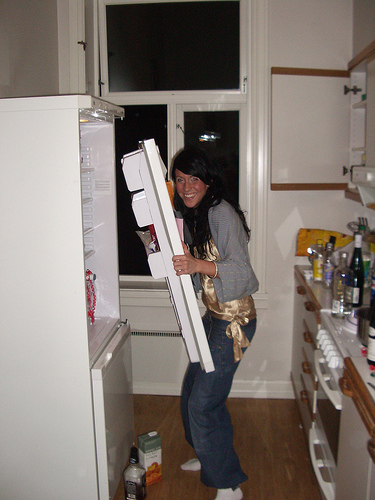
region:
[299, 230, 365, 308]
several bottles on a counter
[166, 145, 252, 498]
woman with dark hair laughing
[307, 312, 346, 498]
an oven door that is white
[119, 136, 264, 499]
woman holding refrigerator door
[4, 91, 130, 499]
refrigerator without a door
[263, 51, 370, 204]
cabinet door that is open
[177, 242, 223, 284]
bracelet on a wrist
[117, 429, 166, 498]
containers on a floor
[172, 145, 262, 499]
woman in white socks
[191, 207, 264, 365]
gold shirt with a bow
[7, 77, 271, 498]
woman in front a refrigerator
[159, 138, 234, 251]
happy woman is smiling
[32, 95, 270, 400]
woman holds a door of refrigerator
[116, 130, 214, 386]
a white door of refrigerator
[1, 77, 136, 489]
the refrigerator is color white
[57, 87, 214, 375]
door of freezer of refrigerator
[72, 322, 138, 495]
door of lower part of refrigerator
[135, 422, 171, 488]
a box of juice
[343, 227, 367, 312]
a bottle of wine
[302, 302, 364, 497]
a stove with white handles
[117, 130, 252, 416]
a woman holding a refrigerator door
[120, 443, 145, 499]
a bottle of alcohol on the floor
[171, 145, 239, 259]
a woman with black hair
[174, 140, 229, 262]
a woman with long hair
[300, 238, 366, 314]
several bottles of on a counter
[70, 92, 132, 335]
a refrigerator with the door off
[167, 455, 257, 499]
a woman wearing white socks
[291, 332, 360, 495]
a white stove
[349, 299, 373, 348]
a silver pot on a stove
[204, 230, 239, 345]
a woman wearing a gold shirt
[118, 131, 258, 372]
Broken refrigerator door held away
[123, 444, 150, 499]
Colorless bottle with a black top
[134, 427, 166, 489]
Box sachet with multiple colors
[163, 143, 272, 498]
Smiling long haired woman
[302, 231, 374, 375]
Bottles arranged on top of a cabinet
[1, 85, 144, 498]
Large refrigerator without an upper door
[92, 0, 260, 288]
Glass window with white panels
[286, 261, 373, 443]
Large cabinet with brown drawer handles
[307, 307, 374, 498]
Cooker unit with white knob controls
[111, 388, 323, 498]
Smooth brown vivyl floor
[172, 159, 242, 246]
Girl has dark hair.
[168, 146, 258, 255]
Girl has long hair.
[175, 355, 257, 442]
Girl wearing blue pants.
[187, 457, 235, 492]
Girl wearing white socks.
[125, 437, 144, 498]
Bottle of jack daniels on ground.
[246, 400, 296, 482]
Brown wood floor in room.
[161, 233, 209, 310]
Woman is holding fridge door.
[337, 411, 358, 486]
White cupboards in room.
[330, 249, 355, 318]
Bottle of absolute vodka on counter.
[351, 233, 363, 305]
Bottle of wine sitting on counter.